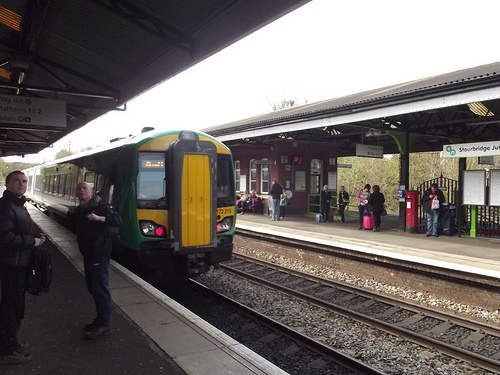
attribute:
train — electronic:
[11, 121, 242, 280]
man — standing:
[64, 182, 123, 339]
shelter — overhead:
[211, 58, 496, 251]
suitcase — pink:
[355, 212, 382, 234]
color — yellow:
[183, 154, 211, 243]